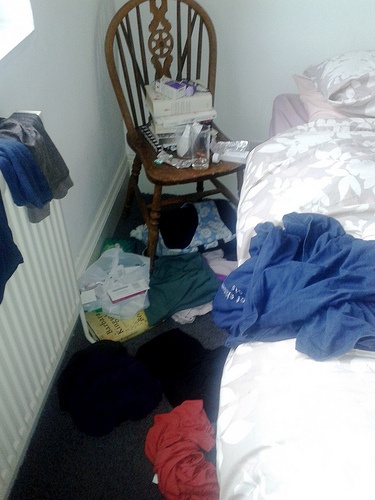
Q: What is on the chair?
A: Clutter.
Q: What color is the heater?
A: White.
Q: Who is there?
A: No one.